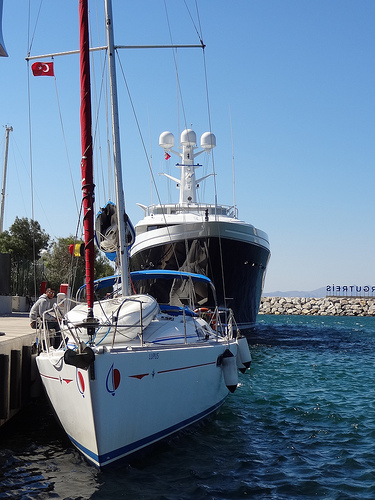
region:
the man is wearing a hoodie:
[29, 294, 53, 321]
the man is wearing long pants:
[30, 320, 57, 332]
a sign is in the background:
[325, 284, 373, 293]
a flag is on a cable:
[31, 58, 55, 77]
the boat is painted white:
[40, 300, 244, 470]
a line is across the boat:
[130, 354, 221, 379]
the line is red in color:
[127, 355, 222, 380]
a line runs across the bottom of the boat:
[96, 378, 238, 462]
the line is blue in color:
[55, 370, 232, 464]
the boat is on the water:
[47, 262, 252, 465]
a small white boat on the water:
[38, 265, 295, 475]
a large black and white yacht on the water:
[129, 134, 280, 349]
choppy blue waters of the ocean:
[262, 388, 362, 498]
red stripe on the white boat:
[134, 356, 217, 389]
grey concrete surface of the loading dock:
[1, 314, 27, 338]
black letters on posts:
[323, 281, 373, 299]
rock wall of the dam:
[270, 296, 372, 313]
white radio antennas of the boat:
[156, 122, 221, 208]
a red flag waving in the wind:
[22, 52, 61, 80]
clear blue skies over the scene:
[256, 34, 364, 139]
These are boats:
[27, 123, 277, 472]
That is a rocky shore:
[261, 294, 374, 319]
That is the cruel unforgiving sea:
[246, 322, 373, 497]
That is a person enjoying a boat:
[24, 283, 66, 340]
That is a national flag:
[26, 55, 62, 80]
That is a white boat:
[27, 259, 266, 470]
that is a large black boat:
[80, 125, 274, 333]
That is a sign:
[322, 275, 373, 302]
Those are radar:
[148, 127, 233, 160]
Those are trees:
[0, 212, 80, 289]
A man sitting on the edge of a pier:
[30, 287, 66, 344]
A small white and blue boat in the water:
[38, 265, 234, 466]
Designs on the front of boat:
[66, 362, 127, 400]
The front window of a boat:
[84, 273, 218, 313]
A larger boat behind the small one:
[127, 130, 271, 327]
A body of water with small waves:
[6, 306, 372, 496]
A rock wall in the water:
[261, 294, 374, 317]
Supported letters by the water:
[324, 282, 373, 292]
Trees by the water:
[0, 219, 115, 302]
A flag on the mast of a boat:
[30, 59, 57, 79]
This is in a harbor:
[11, 34, 296, 374]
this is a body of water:
[250, 391, 353, 490]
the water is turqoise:
[252, 384, 316, 480]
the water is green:
[267, 345, 350, 421]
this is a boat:
[23, 289, 182, 428]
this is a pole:
[59, 164, 146, 305]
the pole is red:
[48, 174, 116, 261]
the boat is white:
[48, 351, 208, 461]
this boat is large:
[137, 188, 337, 407]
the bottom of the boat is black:
[158, 243, 302, 372]